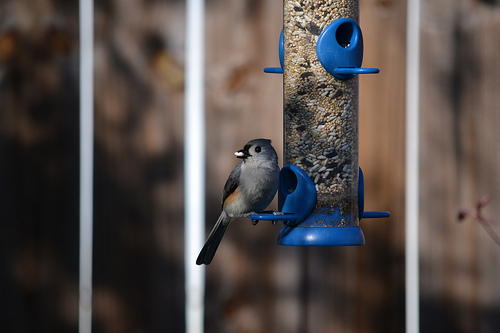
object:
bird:
[196, 138, 283, 265]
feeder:
[252, 0, 394, 246]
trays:
[253, 15, 391, 228]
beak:
[234, 145, 250, 159]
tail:
[196, 212, 226, 267]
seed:
[284, 0, 359, 222]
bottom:
[275, 227, 368, 247]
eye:
[253, 145, 262, 154]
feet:
[247, 209, 286, 226]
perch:
[249, 212, 297, 222]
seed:
[234, 152, 246, 156]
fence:
[78, 0, 422, 331]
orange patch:
[224, 184, 244, 204]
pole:
[79, 1, 93, 331]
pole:
[186, 0, 204, 331]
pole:
[406, 0, 421, 331]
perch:
[334, 67, 383, 75]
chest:
[241, 167, 282, 204]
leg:
[227, 212, 263, 224]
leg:
[259, 209, 284, 223]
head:
[232, 136, 280, 162]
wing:
[222, 163, 243, 200]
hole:
[335, 22, 360, 50]